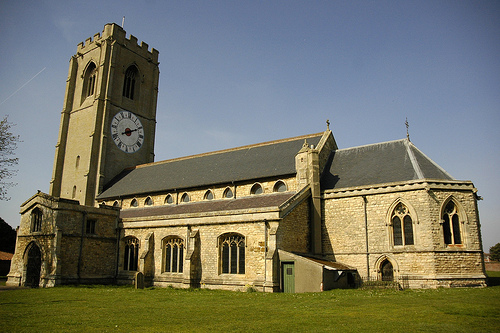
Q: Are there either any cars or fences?
A: No, there are no cars or fences.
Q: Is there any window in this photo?
A: Yes, there are windows.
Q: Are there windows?
A: Yes, there are windows.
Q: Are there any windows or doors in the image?
A: Yes, there are windows.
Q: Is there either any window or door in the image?
A: Yes, there are windows.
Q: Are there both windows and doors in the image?
A: Yes, there are both windows and a door.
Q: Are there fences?
A: No, there are no fences.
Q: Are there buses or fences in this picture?
A: No, there are no fences or buses.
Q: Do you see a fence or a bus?
A: No, there are no fences or buses.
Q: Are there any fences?
A: No, there are no fences.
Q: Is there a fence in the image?
A: No, there are no fences.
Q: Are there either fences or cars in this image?
A: No, there are no fences or cars.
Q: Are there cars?
A: No, there are no cars.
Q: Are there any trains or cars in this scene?
A: No, there are no cars or trains.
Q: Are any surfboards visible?
A: No, there are no surfboards.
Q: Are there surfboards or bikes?
A: No, there are no surfboards or bikes.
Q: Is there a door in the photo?
A: Yes, there is a door.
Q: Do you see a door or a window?
A: Yes, there is a door.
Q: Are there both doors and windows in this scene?
A: Yes, there are both a door and a window.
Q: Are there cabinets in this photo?
A: No, there are no cabinets.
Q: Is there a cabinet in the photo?
A: No, there are no cabinets.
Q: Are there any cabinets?
A: No, there are no cabinets.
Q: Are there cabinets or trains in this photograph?
A: No, there are no cabinets or trains.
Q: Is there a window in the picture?
A: Yes, there is a window.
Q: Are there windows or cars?
A: Yes, there is a window.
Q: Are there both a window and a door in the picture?
A: Yes, there are both a window and a door.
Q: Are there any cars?
A: No, there are no cars.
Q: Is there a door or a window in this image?
A: Yes, there is a window.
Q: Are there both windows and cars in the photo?
A: No, there is a window but no cars.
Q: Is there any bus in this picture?
A: No, there are no buses.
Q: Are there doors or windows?
A: Yes, there is a window.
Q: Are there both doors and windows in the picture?
A: Yes, there are both a window and a door.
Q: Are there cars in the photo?
A: No, there are no cars.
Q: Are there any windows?
A: Yes, there is a window.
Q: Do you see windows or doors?
A: Yes, there is a window.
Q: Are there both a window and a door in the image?
A: Yes, there are both a window and a door.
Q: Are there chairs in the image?
A: No, there are no chairs.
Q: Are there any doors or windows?
A: Yes, there is a window.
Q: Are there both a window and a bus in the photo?
A: No, there is a window but no buses.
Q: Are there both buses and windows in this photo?
A: No, there is a window but no buses.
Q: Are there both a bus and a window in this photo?
A: No, there is a window but no buses.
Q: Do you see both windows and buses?
A: No, there is a window but no buses.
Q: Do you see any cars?
A: No, there are no cars.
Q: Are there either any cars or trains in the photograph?
A: No, there are no cars or trains.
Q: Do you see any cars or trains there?
A: No, there are no cars or trains.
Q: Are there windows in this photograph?
A: Yes, there is a window.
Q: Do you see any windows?
A: Yes, there is a window.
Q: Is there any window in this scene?
A: Yes, there is a window.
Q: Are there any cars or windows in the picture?
A: Yes, there is a window.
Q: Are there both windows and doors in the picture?
A: Yes, there are both a window and a door.